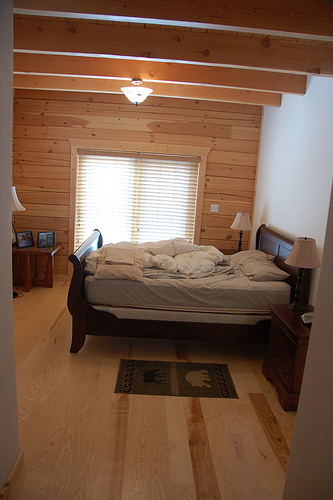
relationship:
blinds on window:
[84, 165, 206, 248] [51, 118, 218, 302]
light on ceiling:
[121, 79, 153, 119] [18, 9, 305, 125]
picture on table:
[16, 226, 62, 250] [12, 241, 62, 289]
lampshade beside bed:
[228, 203, 257, 261] [82, 221, 286, 331]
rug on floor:
[117, 360, 245, 405] [109, 401, 282, 492]